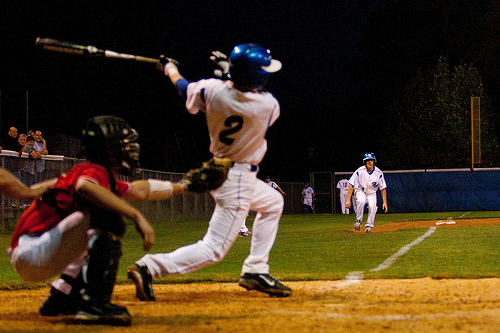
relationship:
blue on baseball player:
[212, 108, 249, 145] [126, 24, 301, 303]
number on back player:
[215, 111, 245, 147] [127, 40, 291, 296]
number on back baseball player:
[215, 111, 245, 147] [126, 44, 292, 301]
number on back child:
[219, 114, 245, 145] [6, 115, 235, 322]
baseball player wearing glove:
[134, 38, 307, 295] [158, 57, 178, 78]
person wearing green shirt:
[19, 133, 47, 160] [22, 142, 39, 155]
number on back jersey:
[219, 114, 245, 145] [186, 78, 281, 166]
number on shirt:
[219, 114, 245, 145] [181, 74, 283, 163]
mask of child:
[87, 124, 157, 169] [10, 126, 234, 323]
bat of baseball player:
[36, 32, 160, 64] [127, 44, 292, 302]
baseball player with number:
[127, 44, 292, 302] [219, 114, 245, 145]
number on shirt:
[219, 114, 245, 145] [166, 73, 281, 164]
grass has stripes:
[277, 208, 498, 280] [351, 220, 441, 276]